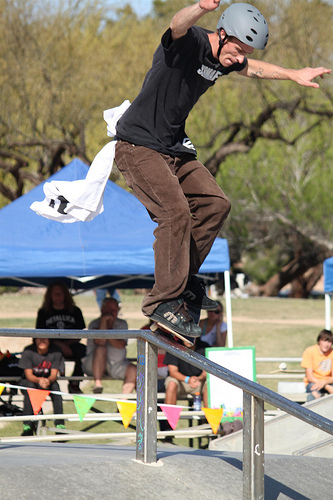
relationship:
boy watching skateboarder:
[299, 328, 332, 399] [112, 1, 331, 337]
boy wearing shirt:
[299, 328, 332, 399] [299, 344, 331, 385]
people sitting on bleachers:
[0, 263, 332, 435] [9, 338, 223, 453]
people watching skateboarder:
[0, 263, 332, 435] [112, 1, 331, 337]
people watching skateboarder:
[2, 263, 332, 469] [33, 1, 326, 356]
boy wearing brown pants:
[102, 1, 332, 351] [112, 130, 233, 317]